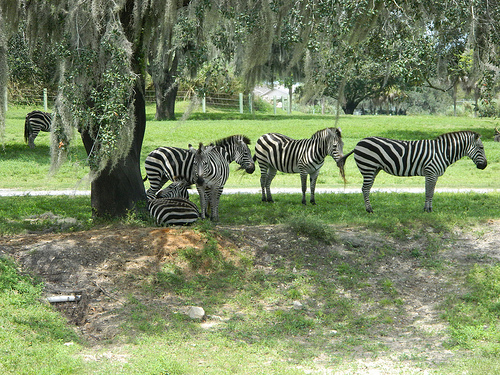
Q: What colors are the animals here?
A: Black and White.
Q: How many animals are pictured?
A: Six.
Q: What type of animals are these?
A: Zebras.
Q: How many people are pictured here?
A: Zero.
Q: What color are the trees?
A: Green.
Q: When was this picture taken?
A: Daytime.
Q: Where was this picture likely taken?
A: A Zoo.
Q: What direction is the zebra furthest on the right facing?
A: Right.